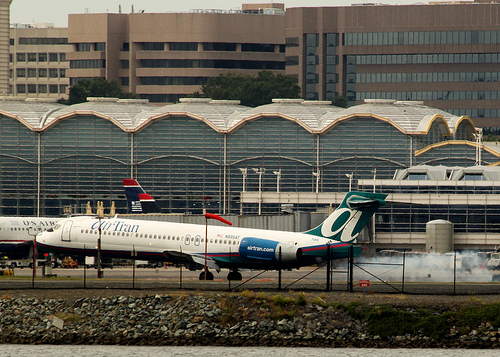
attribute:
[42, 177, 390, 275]
jet — engine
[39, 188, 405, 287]
jet — white 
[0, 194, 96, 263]
jet — white 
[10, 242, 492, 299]
fence — chain link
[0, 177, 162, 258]
airplane — US Air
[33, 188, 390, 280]
jet — AirTran